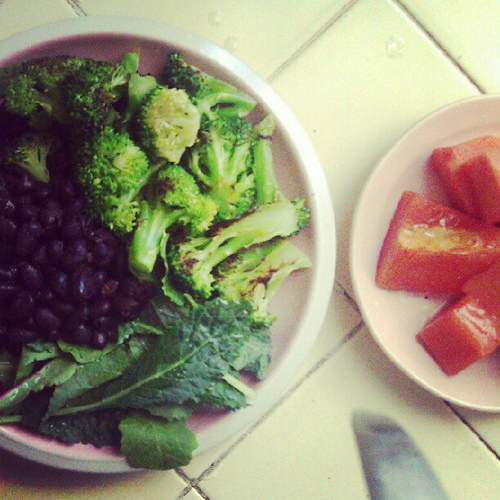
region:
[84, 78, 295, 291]
Broccoli in the bowl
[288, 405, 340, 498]
The white tile beneath the food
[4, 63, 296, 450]
Food in a white bowl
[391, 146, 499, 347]
Cut tomatoes on a plate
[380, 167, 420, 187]
A plate beneatht the tomatoes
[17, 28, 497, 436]
Food above white tiles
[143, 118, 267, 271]
Broccoli near some tomatoes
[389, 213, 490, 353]
Tomatoes near the broccoli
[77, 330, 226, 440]
Lettuce by the broccoli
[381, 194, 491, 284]
The tomato has been cut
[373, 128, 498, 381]
fruit on the plate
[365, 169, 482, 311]
fruit on the plate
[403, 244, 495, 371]
fruit on the plate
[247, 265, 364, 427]
the bowl is white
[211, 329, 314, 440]
the bowl is white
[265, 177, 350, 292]
the bowl is white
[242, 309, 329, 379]
the bowl is white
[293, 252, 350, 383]
the bowl is white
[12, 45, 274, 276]
broccoli on white plate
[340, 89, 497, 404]
chunks of tomato on white plate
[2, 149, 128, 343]
black beans next to broccoli on plate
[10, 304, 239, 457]
leafy greens on white plate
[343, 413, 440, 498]
tip of knife next to white plate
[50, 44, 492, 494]
white tile plates are sitting on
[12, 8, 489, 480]
two white dishes holding food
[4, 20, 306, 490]
white bowl holding three different foods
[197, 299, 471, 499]
grout of white tiles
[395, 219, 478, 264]
yellow blob in tomato slice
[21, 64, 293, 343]
the broccoli is green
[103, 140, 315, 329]
the broccoli is green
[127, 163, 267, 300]
the broccoli is green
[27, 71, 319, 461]
vegetables in a bowl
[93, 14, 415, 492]
vegetables in a bowl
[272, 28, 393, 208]
the counter top is white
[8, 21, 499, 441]
two white plates of food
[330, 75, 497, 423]
tomato wedges on white plate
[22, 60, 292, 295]
pieces of broccoli on white plate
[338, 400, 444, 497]
silver object next to plate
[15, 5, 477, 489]
white tiles with dark grout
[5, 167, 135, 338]
black beans on white plate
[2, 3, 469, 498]
white tile underneath plates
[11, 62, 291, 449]
three vegetables on white plate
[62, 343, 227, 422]
stem of green leaf